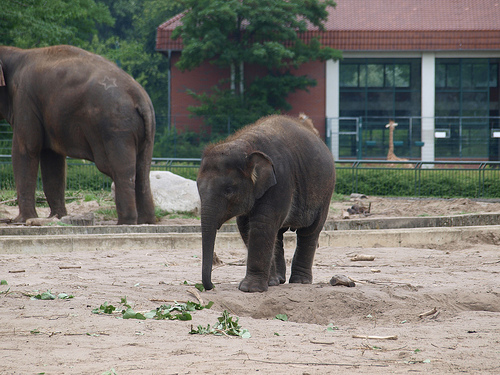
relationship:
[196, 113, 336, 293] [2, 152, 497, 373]
elephant at zoo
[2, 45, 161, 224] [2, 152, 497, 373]
elephant at zoo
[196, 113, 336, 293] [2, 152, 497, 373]
elephant in dirt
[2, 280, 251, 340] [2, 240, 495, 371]
leaves on ground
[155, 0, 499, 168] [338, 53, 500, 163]
bar has windows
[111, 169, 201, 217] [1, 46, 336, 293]
boulder behind elephants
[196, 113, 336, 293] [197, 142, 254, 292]
elephant has head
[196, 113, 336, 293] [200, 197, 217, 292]
elephant has trunk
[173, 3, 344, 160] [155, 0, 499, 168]
tree in front of bar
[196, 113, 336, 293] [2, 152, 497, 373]
elephant on sand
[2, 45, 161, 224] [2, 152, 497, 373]
elephant on sand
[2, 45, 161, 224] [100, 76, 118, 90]
elephant has star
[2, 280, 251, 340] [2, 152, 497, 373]
leaves are on sand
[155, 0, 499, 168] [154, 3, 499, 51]
bar has roof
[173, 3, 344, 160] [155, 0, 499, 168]
tree beside bar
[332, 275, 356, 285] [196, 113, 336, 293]
rock beside elephant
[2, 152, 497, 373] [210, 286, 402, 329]
sand has hole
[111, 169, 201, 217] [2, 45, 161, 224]
boulder beyond elephant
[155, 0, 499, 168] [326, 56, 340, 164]
bar has column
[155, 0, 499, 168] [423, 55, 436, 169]
bar has column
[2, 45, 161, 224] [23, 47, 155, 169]
elephant has back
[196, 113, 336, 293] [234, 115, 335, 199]
elephant has back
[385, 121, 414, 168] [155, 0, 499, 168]
giraffe close to bar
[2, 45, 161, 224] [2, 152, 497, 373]
elephant in pen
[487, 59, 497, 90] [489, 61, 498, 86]
window has part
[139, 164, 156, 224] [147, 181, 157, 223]
leg has edge